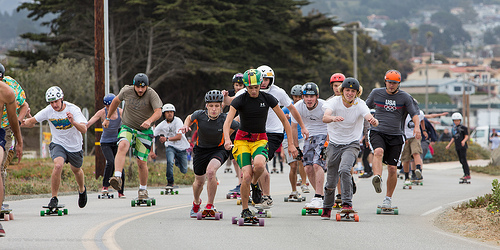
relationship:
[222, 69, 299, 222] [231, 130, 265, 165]
people wearing bob marley colors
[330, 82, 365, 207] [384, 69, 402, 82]
man wearing helmet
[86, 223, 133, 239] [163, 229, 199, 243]
line on road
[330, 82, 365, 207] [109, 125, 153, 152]
man wearing shorts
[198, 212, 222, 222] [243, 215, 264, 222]
wheels attached to skateboard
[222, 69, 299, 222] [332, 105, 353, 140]
people wearing shirt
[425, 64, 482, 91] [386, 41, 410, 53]
city on hill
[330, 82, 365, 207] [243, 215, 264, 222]
man using skateboard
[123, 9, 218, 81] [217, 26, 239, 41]
trees are full of leaves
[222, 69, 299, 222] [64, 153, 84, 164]
people wearing jeans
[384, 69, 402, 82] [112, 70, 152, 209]
helmet on person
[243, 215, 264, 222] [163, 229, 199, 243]
skateboard on road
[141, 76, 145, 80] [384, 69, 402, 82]
slots are on helmet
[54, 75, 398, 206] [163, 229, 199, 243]
people are skateboarding on road